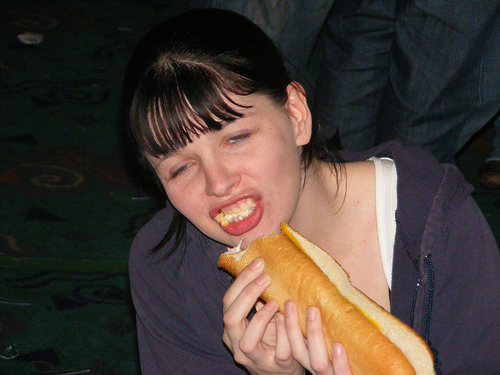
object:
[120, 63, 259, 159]
bangs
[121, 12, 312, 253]
head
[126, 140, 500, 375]
sweater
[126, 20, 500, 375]
girl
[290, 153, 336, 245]
neck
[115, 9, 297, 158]
dark hair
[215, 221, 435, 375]
bun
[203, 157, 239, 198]
nose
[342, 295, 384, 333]
mustard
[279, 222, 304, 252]
mustard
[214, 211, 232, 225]
bun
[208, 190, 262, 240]
mouth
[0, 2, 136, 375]
carpet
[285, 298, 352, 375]
hand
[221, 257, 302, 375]
hand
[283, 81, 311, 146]
ear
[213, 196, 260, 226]
teeth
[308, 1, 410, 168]
leg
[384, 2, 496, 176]
leg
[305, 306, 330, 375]
finger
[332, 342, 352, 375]
finger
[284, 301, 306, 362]
finger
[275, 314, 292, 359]
finger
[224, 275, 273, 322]
finger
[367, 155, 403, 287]
shirt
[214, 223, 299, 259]
bite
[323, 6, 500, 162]
pair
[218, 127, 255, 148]
eye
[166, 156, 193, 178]
eye